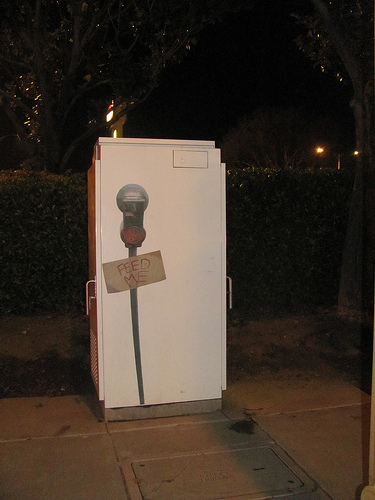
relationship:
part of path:
[67, 438, 222, 489] [7, 377, 375, 499]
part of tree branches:
[104, 27, 127, 66] [0, 2, 211, 137]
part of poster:
[147, 268, 159, 276] [98, 249, 179, 293]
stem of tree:
[335, 111, 374, 319] [283, 6, 374, 316]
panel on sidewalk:
[118, 437, 317, 498] [7, 377, 375, 499]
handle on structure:
[121, 224, 150, 247] [77, 127, 239, 424]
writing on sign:
[118, 258, 155, 287] [98, 249, 179, 293]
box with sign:
[77, 127, 239, 424] [98, 249, 179, 293]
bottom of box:
[96, 395, 228, 424] [77, 127, 239, 424]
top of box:
[86, 131, 222, 166] [77, 127, 239, 424]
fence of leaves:
[1, 172, 346, 317] [289, 192, 301, 231]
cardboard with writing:
[101, 182, 167, 407] [118, 258, 155, 287]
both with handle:
[77, 127, 239, 424] [83, 276, 96, 316]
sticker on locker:
[116, 182, 156, 410] [77, 127, 239, 424]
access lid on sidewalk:
[118, 437, 317, 498] [7, 377, 375, 499]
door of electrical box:
[85, 164, 106, 401] [77, 127, 239, 424]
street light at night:
[311, 145, 365, 160] [225, 35, 296, 103]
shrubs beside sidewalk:
[1, 172, 346, 317] [7, 377, 375, 499]